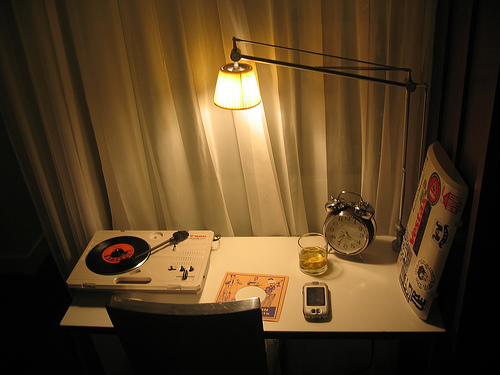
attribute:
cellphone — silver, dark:
[288, 265, 375, 356]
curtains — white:
[1, 0, 499, 300]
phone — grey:
[303, 270, 333, 322]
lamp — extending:
[211, 77, 349, 147]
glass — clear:
[290, 231, 328, 273]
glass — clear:
[296, 228, 330, 278]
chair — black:
[108, 295, 279, 373]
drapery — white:
[0, 0, 499, 373]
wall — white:
[5, 5, 492, 284]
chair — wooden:
[125, 175, 406, 342]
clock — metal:
[312, 186, 385, 258]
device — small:
[303, 282, 332, 322]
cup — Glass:
[295, 230, 330, 275]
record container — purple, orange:
[192, 266, 284, 321]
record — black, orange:
[82, 235, 150, 280]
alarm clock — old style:
[317, 184, 383, 264]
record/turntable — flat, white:
[64, 224, 216, 296]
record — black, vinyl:
[82, 230, 153, 281]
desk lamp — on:
[212, 36, 427, 253]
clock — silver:
[317, 194, 377, 259]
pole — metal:
[250, 39, 404, 251]